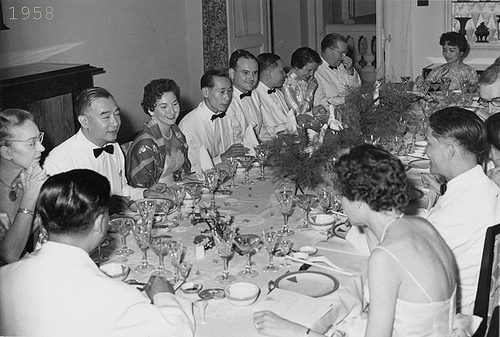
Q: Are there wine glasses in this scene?
A: Yes, there is a wine glass.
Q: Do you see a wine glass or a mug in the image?
A: Yes, there is a wine glass.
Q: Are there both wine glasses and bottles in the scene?
A: No, there is a wine glass but no bottles.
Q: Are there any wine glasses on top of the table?
A: Yes, there is a wine glass on top of the table.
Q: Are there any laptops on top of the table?
A: No, there is a wine glass on top of the table.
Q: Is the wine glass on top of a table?
A: Yes, the wine glass is on top of a table.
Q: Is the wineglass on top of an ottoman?
A: No, the wineglass is on top of a table.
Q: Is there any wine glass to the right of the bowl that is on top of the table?
A: No, the wine glass is to the left of the bowl.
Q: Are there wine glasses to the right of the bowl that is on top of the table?
A: No, the wine glass is to the left of the bowl.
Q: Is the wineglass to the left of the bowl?
A: Yes, the wineglass is to the left of the bowl.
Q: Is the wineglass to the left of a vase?
A: No, the wineglass is to the left of the bowl.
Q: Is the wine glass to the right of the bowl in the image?
A: No, the wine glass is to the left of the bowl.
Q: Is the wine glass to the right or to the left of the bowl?
A: The wine glass is to the left of the bowl.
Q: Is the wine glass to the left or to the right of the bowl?
A: The wine glass is to the left of the bowl.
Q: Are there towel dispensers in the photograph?
A: No, there are no towel dispensers.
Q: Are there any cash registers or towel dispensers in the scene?
A: No, there are no towel dispensers or cash registers.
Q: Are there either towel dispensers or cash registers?
A: No, there are no towel dispensers or cash registers.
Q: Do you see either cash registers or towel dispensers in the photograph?
A: No, there are no towel dispensers or cash registers.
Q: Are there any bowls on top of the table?
A: Yes, there is a bowl on top of the table.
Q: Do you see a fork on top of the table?
A: No, there is a bowl on top of the table.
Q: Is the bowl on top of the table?
A: Yes, the bowl is on top of the table.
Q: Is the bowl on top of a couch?
A: No, the bowl is on top of the table.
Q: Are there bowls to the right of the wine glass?
A: Yes, there is a bowl to the right of the wine glass.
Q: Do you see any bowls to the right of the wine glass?
A: Yes, there is a bowl to the right of the wine glass.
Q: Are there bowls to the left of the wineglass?
A: No, the bowl is to the right of the wineglass.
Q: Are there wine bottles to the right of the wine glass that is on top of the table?
A: No, there is a bowl to the right of the wine glass.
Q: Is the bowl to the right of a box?
A: No, the bowl is to the right of the wineglass.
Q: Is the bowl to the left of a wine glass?
A: No, the bowl is to the right of a wine glass.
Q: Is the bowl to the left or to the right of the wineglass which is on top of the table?
A: The bowl is to the right of the wine glass.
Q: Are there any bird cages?
A: No, there are no bird cages.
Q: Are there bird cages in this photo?
A: No, there are no bird cages.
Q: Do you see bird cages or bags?
A: No, there are no bird cages or bags.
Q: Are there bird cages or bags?
A: No, there are no bird cages or bags.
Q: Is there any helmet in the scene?
A: No, there are no helmets.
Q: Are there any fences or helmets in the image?
A: No, there are no helmets or fences.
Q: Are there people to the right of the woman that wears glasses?
A: Yes, there is a person to the right of the woman.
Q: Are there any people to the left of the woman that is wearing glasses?
A: No, the person is to the right of the woman.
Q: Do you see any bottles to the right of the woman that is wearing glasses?
A: No, there is a person to the right of the woman.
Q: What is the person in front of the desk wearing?
A: The person is wearing a tie.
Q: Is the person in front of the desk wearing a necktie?
A: Yes, the person is wearing a necktie.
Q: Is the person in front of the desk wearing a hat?
A: No, the person is wearing a necktie.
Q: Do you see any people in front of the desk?
A: Yes, there is a person in front of the desk.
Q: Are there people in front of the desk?
A: Yes, there is a person in front of the desk.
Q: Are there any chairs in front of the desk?
A: No, there is a person in front of the desk.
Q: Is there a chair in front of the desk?
A: No, there is a person in front of the desk.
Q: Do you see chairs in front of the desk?
A: No, there is a person in front of the desk.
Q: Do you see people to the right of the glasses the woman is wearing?
A: Yes, there is a person to the right of the glasses.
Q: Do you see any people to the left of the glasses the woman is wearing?
A: No, the person is to the right of the glasses.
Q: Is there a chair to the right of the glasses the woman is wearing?
A: No, there is a person to the right of the glasses.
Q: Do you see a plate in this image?
A: Yes, there is a plate.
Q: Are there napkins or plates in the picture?
A: Yes, there is a plate.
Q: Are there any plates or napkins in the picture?
A: Yes, there is a plate.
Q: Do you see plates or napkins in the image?
A: Yes, there is a plate.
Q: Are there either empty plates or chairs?
A: Yes, there is an empty plate.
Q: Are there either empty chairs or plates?
A: Yes, there is an empty plate.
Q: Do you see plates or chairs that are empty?
A: Yes, the plate is empty.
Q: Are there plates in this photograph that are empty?
A: Yes, there is an empty plate.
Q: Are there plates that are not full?
A: Yes, there is a empty plate.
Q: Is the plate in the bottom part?
A: Yes, the plate is in the bottom of the image.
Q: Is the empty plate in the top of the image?
A: No, the plate is in the bottom of the image.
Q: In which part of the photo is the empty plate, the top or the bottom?
A: The plate is in the bottom of the image.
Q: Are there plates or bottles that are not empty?
A: No, there is a plate but it is empty.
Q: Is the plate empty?
A: Yes, the plate is empty.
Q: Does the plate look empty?
A: Yes, the plate is empty.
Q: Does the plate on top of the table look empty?
A: Yes, the plate is empty.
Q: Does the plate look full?
A: No, the plate is empty.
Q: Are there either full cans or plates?
A: No, there is a plate but it is empty.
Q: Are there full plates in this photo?
A: No, there is a plate but it is empty.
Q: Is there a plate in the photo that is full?
A: No, there is a plate but it is empty.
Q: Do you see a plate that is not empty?
A: No, there is a plate but it is empty.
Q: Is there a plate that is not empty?
A: No, there is a plate but it is empty.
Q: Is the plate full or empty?
A: The plate is empty.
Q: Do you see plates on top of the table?
A: Yes, there is a plate on top of the table.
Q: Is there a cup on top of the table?
A: No, there is a plate on top of the table.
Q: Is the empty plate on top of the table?
A: Yes, the plate is on top of the table.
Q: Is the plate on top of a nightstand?
A: No, the plate is on top of the table.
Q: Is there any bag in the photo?
A: No, there are no bags.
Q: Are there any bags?
A: No, there are no bags.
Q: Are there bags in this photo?
A: No, there are no bags.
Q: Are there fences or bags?
A: No, there are no bags or fences.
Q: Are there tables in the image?
A: Yes, there is a table.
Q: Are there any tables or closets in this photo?
A: Yes, there is a table.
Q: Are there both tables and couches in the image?
A: No, there is a table but no couches.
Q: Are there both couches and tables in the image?
A: No, there is a table but no couches.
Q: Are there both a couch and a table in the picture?
A: No, there is a table but no couches.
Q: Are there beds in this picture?
A: No, there are no beds.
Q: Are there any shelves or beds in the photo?
A: No, there are no beds or shelves.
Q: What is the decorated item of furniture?
A: The piece of furniture is a table.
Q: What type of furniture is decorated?
A: The furniture is a table.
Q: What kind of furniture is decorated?
A: The furniture is a table.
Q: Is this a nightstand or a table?
A: This is a table.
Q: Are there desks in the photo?
A: Yes, there is a desk.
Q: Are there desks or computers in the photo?
A: Yes, there is a desk.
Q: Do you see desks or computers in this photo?
A: Yes, there is a desk.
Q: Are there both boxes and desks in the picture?
A: No, there is a desk but no boxes.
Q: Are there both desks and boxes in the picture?
A: No, there is a desk but no boxes.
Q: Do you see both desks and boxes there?
A: No, there is a desk but no boxes.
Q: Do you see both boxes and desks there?
A: No, there is a desk but no boxes.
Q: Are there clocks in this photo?
A: No, there are no clocks.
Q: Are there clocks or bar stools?
A: No, there are no clocks or bar stools.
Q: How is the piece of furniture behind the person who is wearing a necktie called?
A: The piece of furniture is a desk.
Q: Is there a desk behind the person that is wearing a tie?
A: Yes, there is a desk behind the person.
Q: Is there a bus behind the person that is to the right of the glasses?
A: No, there is a desk behind the person.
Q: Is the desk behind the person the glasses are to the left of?
A: Yes, the desk is behind the person.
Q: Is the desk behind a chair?
A: No, the desk is behind the person.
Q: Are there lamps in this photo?
A: No, there are no lamps.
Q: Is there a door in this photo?
A: Yes, there is a door.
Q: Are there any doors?
A: Yes, there is a door.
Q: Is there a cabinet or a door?
A: Yes, there is a door.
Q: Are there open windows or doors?
A: Yes, there is an open door.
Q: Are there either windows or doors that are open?
A: Yes, the door is open.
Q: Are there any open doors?
A: Yes, there is an open door.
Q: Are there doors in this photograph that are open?
A: Yes, there is a door that is open.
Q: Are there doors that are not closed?
A: Yes, there is a open door.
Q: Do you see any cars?
A: No, there are no cars.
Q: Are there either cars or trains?
A: No, there are no cars or trains.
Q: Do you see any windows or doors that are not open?
A: No, there is a door but it is open.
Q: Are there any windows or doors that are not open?
A: No, there is a door but it is open.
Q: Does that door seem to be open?
A: Yes, the door is open.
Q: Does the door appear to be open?
A: Yes, the door is open.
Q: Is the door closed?
A: No, the door is open.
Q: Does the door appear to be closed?
A: No, the door is open.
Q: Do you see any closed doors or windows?
A: No, there is a door but it is open.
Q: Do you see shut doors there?
A: No, there is a door but it is open.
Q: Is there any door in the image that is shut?
A: No, there is a door but it is open.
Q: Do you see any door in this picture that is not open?
A: No, there is a door but it is open.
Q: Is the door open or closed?
A: The door is open.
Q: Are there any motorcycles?
A: No, there are no motorcycles.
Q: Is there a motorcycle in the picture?
A: No, there are no motorcycles.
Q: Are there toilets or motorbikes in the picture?
A: No, there are no motorbikes or toilets.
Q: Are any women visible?
A: Yes, there is a woman.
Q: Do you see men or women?
A: Yes, there is a woman.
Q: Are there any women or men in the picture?
A: Yes, there is a woman.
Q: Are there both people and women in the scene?
A: Yes, there are both a woman and a person.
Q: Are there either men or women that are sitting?
A: Yes, the woman is sitting.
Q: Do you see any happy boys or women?
A: Yes, there is a happy woman.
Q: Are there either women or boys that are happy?
A: Yes, the woman is happy.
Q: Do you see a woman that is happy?
A: Yes, there is a happy woman.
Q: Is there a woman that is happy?
A: Yes, there is a woman that is happy.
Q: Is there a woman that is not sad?
A: Yes, there is a happy woman.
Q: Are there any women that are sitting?
A: Yes, there is a woman that is sitting.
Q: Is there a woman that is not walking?
A: Yes, there is a woman that is sitting.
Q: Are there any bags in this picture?
A: No, there are no bags.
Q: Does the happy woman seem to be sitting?
A: Yes, the woman is sitting.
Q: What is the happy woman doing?
A: The woman is sitting.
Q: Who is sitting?
A: The woman is sitting.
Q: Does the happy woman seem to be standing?
A: No, the woman is sitting.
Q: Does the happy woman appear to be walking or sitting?
A: The woman is sitting.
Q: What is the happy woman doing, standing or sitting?
A: The woman is sitting.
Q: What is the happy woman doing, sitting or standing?
A: The woman is sitting.